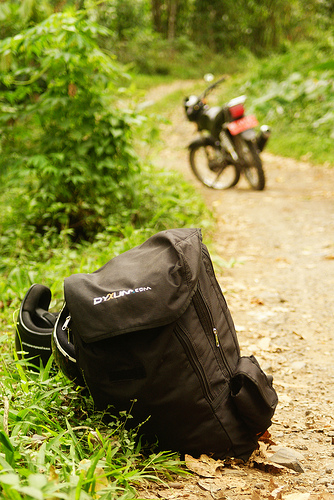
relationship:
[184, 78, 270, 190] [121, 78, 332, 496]
motorbike parked on road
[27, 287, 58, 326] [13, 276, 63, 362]
cushion inside helmet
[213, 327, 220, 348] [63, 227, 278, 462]
tag on side of bag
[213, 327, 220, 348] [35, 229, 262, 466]
tag on side of bag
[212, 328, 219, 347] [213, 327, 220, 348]
tag of tag